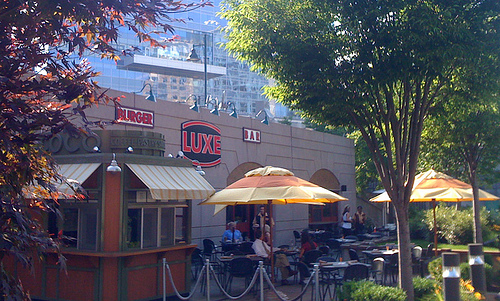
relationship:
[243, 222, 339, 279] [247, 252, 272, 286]
people sitting chair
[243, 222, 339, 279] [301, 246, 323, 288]
people sitting chair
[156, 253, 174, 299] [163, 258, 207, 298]
bar with rope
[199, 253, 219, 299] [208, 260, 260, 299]
bar with rope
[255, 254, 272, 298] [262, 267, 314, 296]
bar with rope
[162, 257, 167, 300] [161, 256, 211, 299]
bar with ropes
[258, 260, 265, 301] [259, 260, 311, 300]
bar with ropes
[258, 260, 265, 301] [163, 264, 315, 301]
bar with chain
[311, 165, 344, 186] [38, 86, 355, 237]
edge of a wall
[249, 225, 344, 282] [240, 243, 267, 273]
people sitting on chair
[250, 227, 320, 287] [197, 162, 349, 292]
people sitting under umbrella